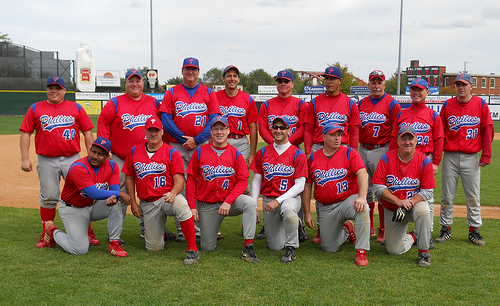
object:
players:
[19, 57, 494, 265]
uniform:
[304, 93, 362, 154]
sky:
[0, 0, 499, 84]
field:
[0, 113, 499, 305]